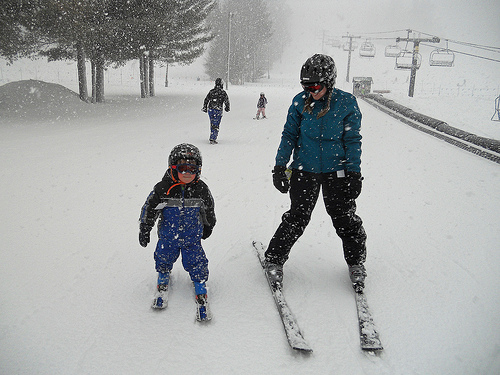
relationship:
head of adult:
[294, 50, 339, 103] [257, 48, 374, 290]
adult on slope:
[257, 48, 374, 290] [5, 3, 484, 371]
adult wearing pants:
[264, 50, 368, 297] [244, 161, 414, 285]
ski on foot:
[354, 283, 383, 351] [314, 190, 390, 290]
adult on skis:
[264, 50, 368, 297] [244, 234, 387, 359]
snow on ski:
[288, 310, 295, 340] [243, 227, 319, 356]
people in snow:
[201, 74, 274, 151] [6, 5, 494, 373]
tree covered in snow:
[4, 1, 211, 108] [40, 5, 186, 59]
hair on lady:
[297, 84, 340, 120] [252, 34, 396, 294]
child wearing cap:
[136, 142, 218, 299] [168, 142, 205, 168]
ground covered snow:
[28, 210, 120, 363] [70, 301, 140, 350]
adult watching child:
[264, 50, 368, 297] [135, 142, 218, 295]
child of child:
[135, 142, 218, 295] [135, 142, 218, 295]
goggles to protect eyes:
[171, 156, 202, 172] [179, 175, 197, 182]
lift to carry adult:
[341, 31, 460, 78] [264, 50, 368, 297]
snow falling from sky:
[40, 116, 124, 286] [15, 5, 488, 65]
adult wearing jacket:
[264, 50, 368, 297] [270, 98, 364, 166]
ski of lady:
[251, 240, 316, 352] [251, 39, 419, 370]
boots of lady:
[259, 259, 370, 289] [251, 39, 419, 370]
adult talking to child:
[264, 50, 368, 297] [124, 129, 258, 352]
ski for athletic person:
[257, 238, 316, 358] [242, 39, 420, 360]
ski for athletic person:
[349, 283, 401, 360] [248, 51, 419, 349]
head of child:
[154, 141, 214, 187] [120, 128, 234, 346]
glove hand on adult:
[267, 166, 302, 191] [248, 44, 404, 351]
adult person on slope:
[188, 65, 232, 144] [0, 83, 499, 373]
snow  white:
[0, 80, 499, 374] [41, 186, 77, 231]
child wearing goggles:
[135, 142, 218, 295] [164, 153, 212, 174]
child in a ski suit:
[135, 142, 218, 295] [129, 174, 234, 280]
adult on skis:
[264, 50, 368, 297] [250, 223, 414, 360]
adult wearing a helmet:
[264, 50, 368, 297] [298, 50, 334, 89]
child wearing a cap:
[136, 142, 218, 299] [168, 142, 203, 186]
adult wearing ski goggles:
[264, 50, 368, 297] [299, 78, 329, 94]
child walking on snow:
[249, 93, 272, 120] [2, 80, 497, 370]